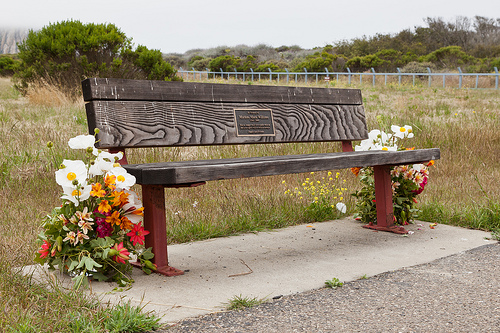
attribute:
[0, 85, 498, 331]
grass — tall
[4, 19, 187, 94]
evergreen bush — lone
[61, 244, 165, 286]
leaves — green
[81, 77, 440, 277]
bench — reddish brown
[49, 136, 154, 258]
flower — beautiful, yellow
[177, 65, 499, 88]
fence — grey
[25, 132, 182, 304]
flower — white, yellow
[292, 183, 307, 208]
flower — yellow, wild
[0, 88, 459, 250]
grass — tall, dried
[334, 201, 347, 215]
flower — white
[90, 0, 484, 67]
sky — overcast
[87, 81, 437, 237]
wooden bench — brown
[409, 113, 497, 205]
grass — dry, brown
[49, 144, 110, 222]
flower — white and yellow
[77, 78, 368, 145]
bench — wood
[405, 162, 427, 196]
flowers — yellow, white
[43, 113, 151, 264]
flowers — white, yellow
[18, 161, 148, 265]
flower — beautiful, pink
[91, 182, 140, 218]
flower — yellow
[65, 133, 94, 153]
flower — colorful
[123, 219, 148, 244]
flower — colorful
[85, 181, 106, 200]
flower — colorful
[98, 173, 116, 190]
flower — colorful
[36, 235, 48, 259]
flower — colorful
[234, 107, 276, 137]
plaque — memorial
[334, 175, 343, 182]
flowers — yellow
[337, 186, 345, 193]
flowers — yellow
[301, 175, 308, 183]
flowers — yellow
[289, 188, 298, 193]
flowers — yellow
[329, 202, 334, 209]
flowers — yellow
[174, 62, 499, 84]
fence — metal, grey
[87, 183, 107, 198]
flower — yellow, beautiful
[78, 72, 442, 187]
wood — weathered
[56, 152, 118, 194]
flower — yellow, beautiful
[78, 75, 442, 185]
bench — wooden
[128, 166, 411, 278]
legs — metal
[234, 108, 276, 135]
plaque — metal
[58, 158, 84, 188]
flower — white, yellow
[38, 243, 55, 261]
flower — red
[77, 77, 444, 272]
seat — wooden, old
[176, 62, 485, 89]
poles — bent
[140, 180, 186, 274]
leg — metal, red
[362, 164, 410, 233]
leg — metal, red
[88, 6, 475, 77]
cover — cloud